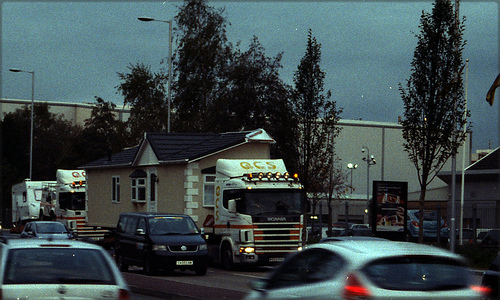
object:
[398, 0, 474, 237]
tree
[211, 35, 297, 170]
tree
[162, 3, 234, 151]
tree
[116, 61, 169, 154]
tree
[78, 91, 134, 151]
tree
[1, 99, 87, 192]
tree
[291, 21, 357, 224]
tree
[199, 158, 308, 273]
semi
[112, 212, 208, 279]
van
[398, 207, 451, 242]
car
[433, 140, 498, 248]
building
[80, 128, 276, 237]
house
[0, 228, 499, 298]
road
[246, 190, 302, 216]
windshield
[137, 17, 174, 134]
lightpole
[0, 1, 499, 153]
sky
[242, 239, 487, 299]
car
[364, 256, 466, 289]
window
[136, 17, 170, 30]
street light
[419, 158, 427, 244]
trunk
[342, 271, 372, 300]
light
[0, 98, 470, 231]
warehouse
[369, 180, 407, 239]
sign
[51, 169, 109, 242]
semi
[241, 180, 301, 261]
front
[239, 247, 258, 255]
headlights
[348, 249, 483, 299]
back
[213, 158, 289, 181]
spoiler